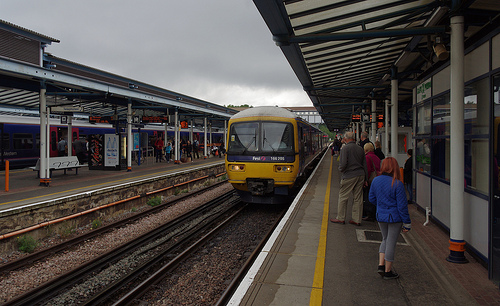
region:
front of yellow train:
[224, 109, 299, 191]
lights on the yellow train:
[284, 163, 294, 174]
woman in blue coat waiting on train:
[372, 154, 410, 277]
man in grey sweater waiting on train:
[335, 133, 367, 224]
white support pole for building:
[444, 17, 468, 264]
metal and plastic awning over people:
[277, 2, 408, 67]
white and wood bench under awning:
[45, 154, 81, 170]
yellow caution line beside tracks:
[320, 160, 337, 230]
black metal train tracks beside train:
[211, 202, 248, 226]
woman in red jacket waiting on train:
[365, 141, 379, 183]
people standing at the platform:
[322, 115, 380, 232]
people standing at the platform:
[324, 117, 370, 172]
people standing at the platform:
[329, 112, 419, 267]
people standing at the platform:
[137, 122, 219, 169]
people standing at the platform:
[138, 109, 189, 156]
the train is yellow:
[202, 79, 331, 235]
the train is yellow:
[197, 84, 298, 178]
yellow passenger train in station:
[216, 93, 301, 200]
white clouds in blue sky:
[54, 6, 101, 36]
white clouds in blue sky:
[90, 33, 143, 74]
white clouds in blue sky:
[123, 17, 164, 45]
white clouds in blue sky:
[154, 6, 206, 37]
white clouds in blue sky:
[200, 9, 247, 53]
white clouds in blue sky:
[192, 57, 255, 95]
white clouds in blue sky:
[223, 49, 280, 87]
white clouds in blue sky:
[128, 25, 183, 75]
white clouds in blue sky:
[120, 11, 194, 58]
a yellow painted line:
[313, 188, 350, 274]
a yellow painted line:
[297, 237, 351, 304]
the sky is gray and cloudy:
[84, 22, 155, 74]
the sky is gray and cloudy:
[160, 19, 284, 114]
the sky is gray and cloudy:
[59, 12, 246, 109]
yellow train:
[221, 104, 300, 188]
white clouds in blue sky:
[64, 11, 111, 44]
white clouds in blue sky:
[113, 16, 165, 69]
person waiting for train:
[378, 144, 411, 267]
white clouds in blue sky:
[137, 22, 173, 55]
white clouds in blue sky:
[175, 55, 224, 80]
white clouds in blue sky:
[92, 22, 147, 61]